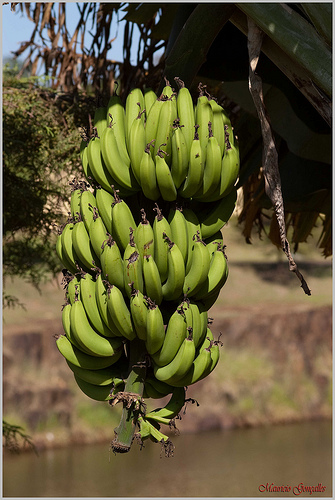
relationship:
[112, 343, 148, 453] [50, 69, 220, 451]
stalk on bananas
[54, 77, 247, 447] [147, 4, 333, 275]
bananas hanging from tree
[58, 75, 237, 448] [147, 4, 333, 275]
banana bunch hanging from tree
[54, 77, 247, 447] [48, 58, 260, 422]
bananas growing on tree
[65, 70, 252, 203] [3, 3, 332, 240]
bananas hanging from tree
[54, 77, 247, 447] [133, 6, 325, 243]
bananas hanging from tree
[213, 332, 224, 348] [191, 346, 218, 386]
stem on banana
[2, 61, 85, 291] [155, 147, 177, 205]
greenery by banana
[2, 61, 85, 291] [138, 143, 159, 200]
greenery by banana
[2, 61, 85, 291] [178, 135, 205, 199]
greenery by banana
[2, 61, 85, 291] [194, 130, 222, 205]
greenery by banana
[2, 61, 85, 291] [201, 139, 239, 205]
greenery by banana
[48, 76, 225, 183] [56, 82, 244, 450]
green banana in a bunch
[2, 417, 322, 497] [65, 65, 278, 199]
water below bananas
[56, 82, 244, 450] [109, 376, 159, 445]
bunch of bananas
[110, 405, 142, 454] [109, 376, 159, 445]
stalk of bananas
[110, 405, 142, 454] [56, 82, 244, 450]
stalk of bunch